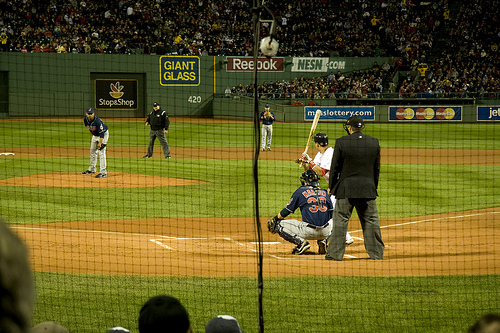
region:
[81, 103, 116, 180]
baseball pitcher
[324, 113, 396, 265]
baseball umpire standing near home plate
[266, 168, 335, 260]
baseball catcher standing by home base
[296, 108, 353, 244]
baseball batter standing on home plate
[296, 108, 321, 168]
Light brown baseball bat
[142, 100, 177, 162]
Baseball coach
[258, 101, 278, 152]
baseball outfielder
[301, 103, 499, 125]
baseball stadium advertisements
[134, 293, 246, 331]
backs of spectators heads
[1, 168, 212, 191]
red clay pitchers mound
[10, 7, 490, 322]
They are playing baseball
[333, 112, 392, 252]
The home plate umpire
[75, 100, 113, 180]
This is the pitcher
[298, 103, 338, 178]
This man is holding a baseball bat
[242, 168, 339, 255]
The catcher is crouched over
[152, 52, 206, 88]
An ad for Giant Glass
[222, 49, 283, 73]
An ad for Reebok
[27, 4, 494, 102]
Many people in the bleachers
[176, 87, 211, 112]
The number 420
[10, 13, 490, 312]
A net behind home plate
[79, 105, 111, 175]
Pitcher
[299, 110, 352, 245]
Person at bat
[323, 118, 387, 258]
Umpire behind the batter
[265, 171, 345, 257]
Catcher behind the batter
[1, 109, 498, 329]
Baseball playing field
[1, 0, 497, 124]
Audience on one side of the baseball field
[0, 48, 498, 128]
Several borders separating the audience from the baseball field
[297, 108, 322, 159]
Wooden baseball bat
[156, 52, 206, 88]
Giant post on the border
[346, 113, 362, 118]
Man wearing black hat.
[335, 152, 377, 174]
Man wearing black jacket.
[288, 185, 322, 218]
Man wearing blue shirt.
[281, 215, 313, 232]
Man wearing gray pants.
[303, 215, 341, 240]
Man wearing dark belt.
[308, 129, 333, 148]
Batter wearing helmet.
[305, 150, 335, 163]
Person wearing white shirt.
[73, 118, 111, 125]
Person wearing blue shirt.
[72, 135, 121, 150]
Person wearing gray pants.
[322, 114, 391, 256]
umpire standing behind catcher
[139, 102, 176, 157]
umpire standing beside second base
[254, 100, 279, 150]
second baseman standing on the field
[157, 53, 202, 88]
yellow and green advertisement sign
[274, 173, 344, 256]
catcher crouched behind home plate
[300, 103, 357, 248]
batter standing ready to swing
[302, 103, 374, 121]
blue sign with white lettering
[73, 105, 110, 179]
pitcher readying on the pitcher's mound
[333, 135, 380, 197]
black coat worn by umpire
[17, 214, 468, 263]
white chalk lines on the field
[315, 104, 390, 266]
umpire standing behind catcher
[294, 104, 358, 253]
batter standing at home plate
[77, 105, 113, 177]
pitcher on mound preparing to pitch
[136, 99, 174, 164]
umpire standing in infield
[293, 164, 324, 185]
catcher wearing black mask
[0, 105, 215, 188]
pitcher standing on dirt mound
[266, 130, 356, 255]
catcher crouching behind batter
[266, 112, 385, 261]
umpire standing behind catcher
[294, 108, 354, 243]
batter holding a wooden bat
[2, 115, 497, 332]
field is green grass and brown dirt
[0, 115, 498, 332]
white painted line on field